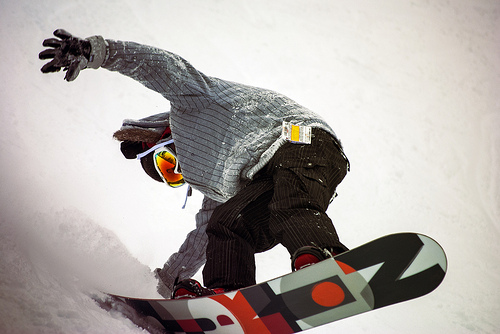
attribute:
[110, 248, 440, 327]
board — multicolor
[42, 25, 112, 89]
gloves — black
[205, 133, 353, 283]
pants — dark brown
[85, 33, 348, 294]
outfit — striped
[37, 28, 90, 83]
glove — black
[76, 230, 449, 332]
snowboard — red and black, white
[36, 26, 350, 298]
snowboarder — bend forward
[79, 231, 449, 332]
snow board — flexing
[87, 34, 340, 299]
jacket — gray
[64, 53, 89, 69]
snow — white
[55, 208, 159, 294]
snow — kicking up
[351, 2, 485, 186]
sky — blue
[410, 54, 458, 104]
sky — blue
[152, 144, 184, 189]
goggles — Reflective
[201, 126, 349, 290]
pants — pinstriped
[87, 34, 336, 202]
shirt — pinstriped, gray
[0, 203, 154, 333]
snow — white, fluffy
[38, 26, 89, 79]
glove — thick, black